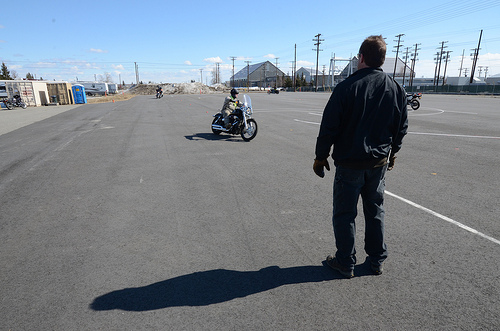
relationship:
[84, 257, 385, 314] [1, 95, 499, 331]
shadow on ground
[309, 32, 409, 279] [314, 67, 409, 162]
man wearing jacket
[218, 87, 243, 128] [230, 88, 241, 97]
man wearing helmet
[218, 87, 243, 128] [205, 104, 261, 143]
man riding motor cycle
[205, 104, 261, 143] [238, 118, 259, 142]
motor cycle has wheel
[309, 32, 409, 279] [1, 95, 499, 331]
man standing on ground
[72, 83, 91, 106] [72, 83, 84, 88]
portapotty has roof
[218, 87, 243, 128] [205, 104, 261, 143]
man on motor cycle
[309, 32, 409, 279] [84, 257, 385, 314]
man has shadow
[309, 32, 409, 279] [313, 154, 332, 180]
man wearing glove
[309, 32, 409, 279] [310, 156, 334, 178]
man has hand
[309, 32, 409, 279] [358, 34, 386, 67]
man has hair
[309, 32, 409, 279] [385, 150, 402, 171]
man has hand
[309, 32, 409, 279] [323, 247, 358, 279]
man has foot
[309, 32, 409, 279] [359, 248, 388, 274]
man has foot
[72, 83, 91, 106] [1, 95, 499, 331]
portapotty on ground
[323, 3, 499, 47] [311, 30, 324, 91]
wires are from pole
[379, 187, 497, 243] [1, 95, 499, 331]
line on ground